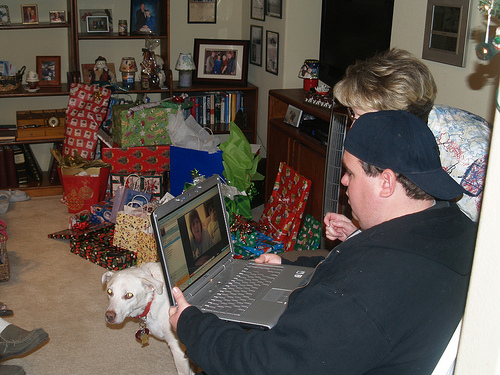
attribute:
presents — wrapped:
[57, 93, 304, 179]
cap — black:
[338, 98, 485, 223]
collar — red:
[107, 251, 158, 358]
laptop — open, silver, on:
[133, 176, 321, 335]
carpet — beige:
[9, 199, 115, 328]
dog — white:
[98, 250, 192, 355]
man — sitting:
[172, 151, 472, 339]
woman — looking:
[309, 46, 492, 183]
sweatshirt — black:
[171, 227, 460, 353]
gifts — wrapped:
[70, 78, 255, 200]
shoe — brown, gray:
[3, 316, 58, 356]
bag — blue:
[169, 147, 242, 208]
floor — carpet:
[24, 203, 95, 362]